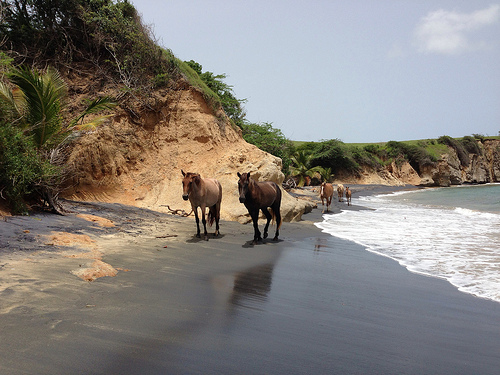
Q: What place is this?
A: It is a beach.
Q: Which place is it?
A: It is a beach.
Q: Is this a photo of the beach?
A: Yes, it is showing the beach.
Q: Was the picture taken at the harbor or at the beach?
A: It was taken at the beach.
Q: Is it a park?
A: No, it is a beach.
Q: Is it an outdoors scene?
A: Yes, it is outdoors.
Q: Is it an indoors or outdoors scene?
A: It is outdoors.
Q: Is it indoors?
A: No, it is outdoors.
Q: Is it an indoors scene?
A: No, it is outdoors.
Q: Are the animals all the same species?
A: Yes, all the animals are horses.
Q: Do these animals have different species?
A: No, all the animals are horses.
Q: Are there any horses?
A: Yes, there is a horse.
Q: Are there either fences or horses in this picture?
A: Yes, there is a horse.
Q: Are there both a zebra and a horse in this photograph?
A: No, there is a horse but no zebras.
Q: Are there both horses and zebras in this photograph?
A: No, there is a horse but no zebras.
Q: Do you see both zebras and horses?
A: No, there is a horse but no zebras.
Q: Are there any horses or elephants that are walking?
A: Yes, the horse is walking.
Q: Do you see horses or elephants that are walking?
A: Yes, the horse is walking.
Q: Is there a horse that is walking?
A: Yes, there is a horse that is walking.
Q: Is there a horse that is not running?
A: Yes, there is a horse that is walking.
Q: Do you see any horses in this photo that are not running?
A: Yes, there is a horse that is walking .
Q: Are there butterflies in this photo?
A: No, there are no butterflies.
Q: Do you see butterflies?
A: No, there are no butterflies.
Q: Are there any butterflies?
A: No, there are no butterflies.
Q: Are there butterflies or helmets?
A: No, there are no butterflies or helmets.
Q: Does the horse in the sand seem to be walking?
A: Yes, the horse is walking.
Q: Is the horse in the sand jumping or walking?
A: The horse is walking.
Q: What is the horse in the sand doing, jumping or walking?
A: The horse is walking.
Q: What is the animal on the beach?
A: The animal is a horse.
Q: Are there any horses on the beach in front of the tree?
A: Yes, there is a horse on the beach.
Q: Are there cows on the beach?
A: No, there is a horse on the beach.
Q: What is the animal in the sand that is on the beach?
A: The animal is a horse.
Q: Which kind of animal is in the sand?
A: The animal is a horse.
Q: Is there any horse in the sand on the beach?
A: Yes, there is a horse in the sand.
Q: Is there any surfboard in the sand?
A: No, there is a horse in the sand.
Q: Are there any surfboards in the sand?
A: No, there is a horse in the sand.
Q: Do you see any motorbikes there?
A: No, there are no motorbikes.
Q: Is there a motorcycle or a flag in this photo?
A: No, there are no motorcycles or flags.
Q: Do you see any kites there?
A: No, there are no kites.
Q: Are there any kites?
A: No, there are no kites.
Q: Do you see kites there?
A: No, there are no kites.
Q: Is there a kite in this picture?
A: No, there are no kites.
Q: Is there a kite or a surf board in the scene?
A: No, there are no kites or surfboards.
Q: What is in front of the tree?
A: The beach is in front of the tree.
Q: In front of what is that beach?
A: The beach is in front of the tree.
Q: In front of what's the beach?
A: The beach is in front of the tree.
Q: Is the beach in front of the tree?
A: Yes, the beach is in front of the tree.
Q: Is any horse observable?
A: Yes, there is a horse.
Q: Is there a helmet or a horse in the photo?
A: Yes, there is a horse.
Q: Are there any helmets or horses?
A: Yes, there is a horse.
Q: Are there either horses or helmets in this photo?
A: Yes, there is a horse.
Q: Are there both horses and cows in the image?
A: No, there is a horse but no cows.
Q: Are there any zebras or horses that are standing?
A: Yes, the horse is standing.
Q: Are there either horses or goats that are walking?
A: Yes, the horse is walking.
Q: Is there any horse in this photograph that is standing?
A: Yes, there is a horse that is standing.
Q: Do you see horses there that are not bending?
A: Yes, there is a horse that is standing .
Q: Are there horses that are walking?
A: Yes, there is a horse that is walking.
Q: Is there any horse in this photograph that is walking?
A: Yes, there is a horse that is walking.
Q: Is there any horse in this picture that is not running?
A: Yes, there is a horse that is walking.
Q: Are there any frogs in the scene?
A: No, there are no frogs.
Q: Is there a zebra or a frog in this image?
A: No, there are no frogs or zebras.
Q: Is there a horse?
A: Yes, there is a horse.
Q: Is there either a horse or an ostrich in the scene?
A: Yes, there is a horse.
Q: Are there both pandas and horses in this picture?
A: No, there is a horse but no pandas.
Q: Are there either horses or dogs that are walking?
A: Yes, the horse is walking.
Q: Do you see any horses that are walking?
A: Yes, there is a horse that is walking.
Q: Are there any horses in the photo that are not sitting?
A: Yes, there is a horse that is walking.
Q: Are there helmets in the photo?
A: No, there are no helmets.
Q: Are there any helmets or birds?
A: No, there are no helmets or birds.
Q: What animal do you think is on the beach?
A: The animal is a horse.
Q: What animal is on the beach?
A: The animal is a horse.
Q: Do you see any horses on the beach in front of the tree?
A: Yes, there is a horse on the beach.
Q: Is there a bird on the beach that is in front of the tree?
A: No, there is a horse on the beach.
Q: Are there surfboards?
A: No, there are no surfboards.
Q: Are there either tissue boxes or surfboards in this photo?
A: No, there are no surfboards or tissue boxes.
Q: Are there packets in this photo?
A: No, there are no packets.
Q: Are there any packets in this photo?
A: No, there are no packets.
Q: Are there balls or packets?
A: No, there are no packets or balls.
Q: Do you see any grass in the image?
A: Yes, there is grass.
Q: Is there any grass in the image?
A: Yes, there is grass.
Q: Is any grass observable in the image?
A: Yes, there is grass.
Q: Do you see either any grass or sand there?
A: Yes, there is grass.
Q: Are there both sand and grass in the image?
A: Yes, there are both grass and sand.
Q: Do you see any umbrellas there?
A: No, there are no umbrellas.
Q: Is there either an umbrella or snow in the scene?
A: No, there are no umbrellas or snow.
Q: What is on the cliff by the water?
A: The grass is on the cliff.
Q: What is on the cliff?
A: The grass is on the cliff.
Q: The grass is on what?
A: The grass is on the cliff.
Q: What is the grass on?
A: The grass is on the cliff.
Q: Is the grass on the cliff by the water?
A: Yes, the grass is on the cliff.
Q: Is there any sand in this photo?
A: Yes, there is sand.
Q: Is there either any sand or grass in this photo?
A: Yes, there is sand.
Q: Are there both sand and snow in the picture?
A: No, there is sand but no snow.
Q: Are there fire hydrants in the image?
A: No, there are no fire hydrants.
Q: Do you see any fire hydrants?
A: No, there are no fire hydrants.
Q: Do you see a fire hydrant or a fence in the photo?
A: No, there are no fire hydrants or fences.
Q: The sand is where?
A: The sand is on the beach.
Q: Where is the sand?
A: The sand is on the beach.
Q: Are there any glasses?
A: No, there are no glasses.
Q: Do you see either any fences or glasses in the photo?
A: No, there are no glasses or fences.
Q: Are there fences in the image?
A: No, there are no fences.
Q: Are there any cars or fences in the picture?
A: No, there are no fences or cars.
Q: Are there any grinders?
A: No, there are no grinders.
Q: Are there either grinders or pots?
A: No, there are no grinders or pots.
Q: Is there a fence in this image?
A: No, there are no fences.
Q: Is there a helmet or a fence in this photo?
A: No, there are no fences or helmets.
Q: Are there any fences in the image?
A: No, there are no fences.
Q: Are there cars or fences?
A: No, there are no fences or cars.